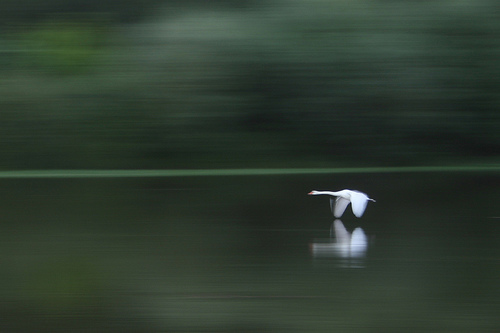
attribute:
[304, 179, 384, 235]
bird — flying, white, goose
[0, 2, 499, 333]
water — calm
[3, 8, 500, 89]
background — green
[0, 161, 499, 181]
line — blurry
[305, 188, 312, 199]
beak — orange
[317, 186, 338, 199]
neck — long, white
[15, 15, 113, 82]
leaves — green, blurry